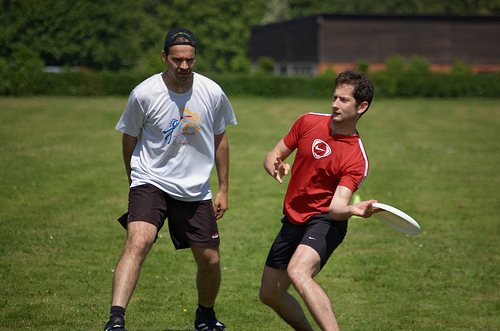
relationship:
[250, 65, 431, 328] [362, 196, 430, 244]
man holding disc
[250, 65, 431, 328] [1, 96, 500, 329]
man in grass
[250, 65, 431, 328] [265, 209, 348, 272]
man in shorts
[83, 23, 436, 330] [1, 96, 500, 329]
people in grass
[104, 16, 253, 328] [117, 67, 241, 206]
person wearing top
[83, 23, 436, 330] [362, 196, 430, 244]
people playing disc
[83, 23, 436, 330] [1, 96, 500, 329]
people are on grass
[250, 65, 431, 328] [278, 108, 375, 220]
man in shirt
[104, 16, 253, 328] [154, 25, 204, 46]
person in hat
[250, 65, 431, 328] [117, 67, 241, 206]
man in top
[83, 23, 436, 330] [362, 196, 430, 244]
people are playing disc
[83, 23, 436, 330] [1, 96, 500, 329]
people on top grass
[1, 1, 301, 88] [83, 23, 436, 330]
trees behind people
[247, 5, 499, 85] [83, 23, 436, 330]
building behind people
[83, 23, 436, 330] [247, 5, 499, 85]
people near building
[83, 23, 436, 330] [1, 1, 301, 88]
people near trees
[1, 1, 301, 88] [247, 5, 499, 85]
trees near building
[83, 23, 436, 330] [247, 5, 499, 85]
people next to building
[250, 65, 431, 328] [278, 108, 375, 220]
man in red shirt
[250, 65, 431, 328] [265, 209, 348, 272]
man in black shorts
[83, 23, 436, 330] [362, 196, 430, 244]
people near disc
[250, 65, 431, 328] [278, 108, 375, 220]
man in a red shirt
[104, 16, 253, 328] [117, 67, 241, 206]
person in a white top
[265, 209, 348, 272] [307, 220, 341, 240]
shorts on man are black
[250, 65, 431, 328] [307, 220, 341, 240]
man wearing black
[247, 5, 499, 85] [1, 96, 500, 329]
building behind grass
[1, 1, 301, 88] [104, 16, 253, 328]
trees behind person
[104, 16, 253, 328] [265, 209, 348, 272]
person in shorts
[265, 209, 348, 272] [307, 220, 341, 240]
shorts are color of black